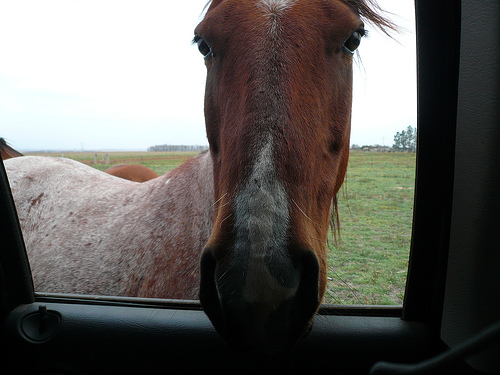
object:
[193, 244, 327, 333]
nose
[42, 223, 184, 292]
stomach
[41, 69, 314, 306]
edge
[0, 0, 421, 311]
window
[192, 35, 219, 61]
eye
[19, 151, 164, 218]
back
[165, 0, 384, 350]
head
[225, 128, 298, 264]
spot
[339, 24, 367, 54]
eyes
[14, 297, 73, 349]
lock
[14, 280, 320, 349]
door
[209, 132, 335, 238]
hair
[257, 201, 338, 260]
whiskers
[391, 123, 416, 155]
trees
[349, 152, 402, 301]
field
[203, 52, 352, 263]
face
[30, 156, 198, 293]
body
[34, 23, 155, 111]
sky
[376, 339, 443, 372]
knob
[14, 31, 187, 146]
clouds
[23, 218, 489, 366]
interior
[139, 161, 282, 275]
patch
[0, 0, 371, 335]
horse